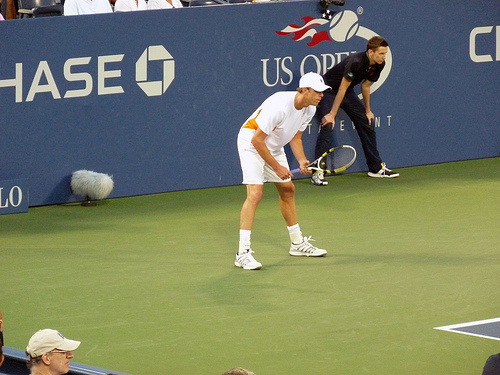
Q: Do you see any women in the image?
A: No, there are no women.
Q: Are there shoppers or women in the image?
A: No, there are no women or shoppers.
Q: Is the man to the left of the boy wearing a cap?
A: Yes, the man is wearing a cap.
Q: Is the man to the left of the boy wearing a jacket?
A: No, the man is wearing a cap.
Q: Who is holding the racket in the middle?
A: The man is holding the tennis racket.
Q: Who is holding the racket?
A: The man is holding the tennis racket.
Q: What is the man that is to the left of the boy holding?
A: The man is holding the racket.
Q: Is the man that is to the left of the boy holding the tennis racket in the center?
A: Yes, the man is holding the tennis racket.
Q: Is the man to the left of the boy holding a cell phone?
A: No, the man is holding the tennis racket.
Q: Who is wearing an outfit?
A: The man is wearing an outfit.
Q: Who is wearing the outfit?
A: The man is wearing an outfit.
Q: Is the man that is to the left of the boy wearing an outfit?
A: Yes, the man is wearing an outfit.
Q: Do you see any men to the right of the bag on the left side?
A: Yes, there is a man to the right of the bag.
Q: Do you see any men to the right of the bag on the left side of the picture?
A: Yes, there is a man to the right of the bag.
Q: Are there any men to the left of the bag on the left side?
A: No, the man is to the right of the bag.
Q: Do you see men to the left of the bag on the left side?
A: No, the man is to the right of the bag.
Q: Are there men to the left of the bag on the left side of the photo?
A: No, the man is to the right of the bag.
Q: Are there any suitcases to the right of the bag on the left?
A: No, there is a man to the right of the bag.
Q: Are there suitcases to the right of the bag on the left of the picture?
A: No, there is a man to the right of the bag.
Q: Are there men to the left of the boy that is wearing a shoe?
A: Yes, there is a man to the left of the boy.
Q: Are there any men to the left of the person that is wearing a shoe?
A: Yes, there is a man to the left of the boy.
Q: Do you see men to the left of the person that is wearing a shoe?
A: Yes, there is a man to the left of the boy.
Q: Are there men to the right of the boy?
A: No, the man is to the left of the boy.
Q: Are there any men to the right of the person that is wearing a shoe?
A: No, the man is to the left of the boy.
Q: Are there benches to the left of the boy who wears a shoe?
A: No, there is a man to the left of the boy.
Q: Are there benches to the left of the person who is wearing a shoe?
A: No, there is a man to the left of the boy.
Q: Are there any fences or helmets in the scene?
A: No, there are no fences or helmets.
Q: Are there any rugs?
A: No, there are no rugs.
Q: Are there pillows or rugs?
A: No, there are no rugs or pillows.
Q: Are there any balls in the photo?
A: Yes, there is a ball.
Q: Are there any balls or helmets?
A: Yes, there is a ball.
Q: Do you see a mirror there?
A: No, there are no mirrors.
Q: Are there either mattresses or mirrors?
A: No, there are no mirrors or mattresses.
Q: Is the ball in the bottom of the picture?
A: No, the ball is in the top of the image.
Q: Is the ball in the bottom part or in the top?
A: The ball is in the top of the image.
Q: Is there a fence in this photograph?
A: No, there are no fences.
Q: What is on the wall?
A: The logo is on the wall.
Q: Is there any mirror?
A: No, there are no mirrors.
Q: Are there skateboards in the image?
A: No, there are no skateboards.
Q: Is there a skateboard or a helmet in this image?
A: No, there are no skateboards or helmets.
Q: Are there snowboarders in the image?
A: No, there are no snowboarders.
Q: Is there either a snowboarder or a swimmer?
A: No, there are no snowboarders or swimmers.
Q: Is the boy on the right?
A: Yes, the boy is on the right of the image.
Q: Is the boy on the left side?
A: No, the boy is on the right of the image.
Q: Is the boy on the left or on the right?
A: The boy is on the right of the image.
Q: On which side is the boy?
A: The boy is on the right of the image.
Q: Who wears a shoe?
A: The boy wears a shoe.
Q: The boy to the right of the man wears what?
A: The boy wears a shoe.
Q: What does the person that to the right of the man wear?
A: The boy wears a shoe.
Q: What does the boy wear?
A: The boy wears a shoe.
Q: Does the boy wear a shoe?
A: Yes, the boy wears a shoe.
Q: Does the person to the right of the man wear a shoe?
A: Yes, the boy wears a shoe.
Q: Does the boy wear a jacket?
A: No, the boy wears a shoe.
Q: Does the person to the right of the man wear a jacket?
A: No, the boy wears a shoe.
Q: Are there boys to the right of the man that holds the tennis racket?
A: Yes, there is a boy to the right of the man.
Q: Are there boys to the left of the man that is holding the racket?
A: No, the boy is to the right of the man.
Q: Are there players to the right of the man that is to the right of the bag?
A: No, there is a boy to the right of the man.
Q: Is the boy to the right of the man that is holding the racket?
A: Yes, the boy is to the right of the man.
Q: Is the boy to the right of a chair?
A: No, the boy is to the right of the man.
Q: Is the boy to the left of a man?
A: No, the boy is to the right of a man.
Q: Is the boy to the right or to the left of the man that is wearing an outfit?
A: The boy is to the right of the man.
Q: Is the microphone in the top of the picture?
A: Yes, the microphone is in the top of the image.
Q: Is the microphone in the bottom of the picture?
A: No, the microphone is in the top of the image.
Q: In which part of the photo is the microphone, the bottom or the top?
A: The microphone is in the top of the image.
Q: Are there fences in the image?
A: No, there are no fences.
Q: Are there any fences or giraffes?
A: No, there are no fences or giraffes.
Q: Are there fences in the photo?
A: No, there are no fences.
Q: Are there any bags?
A: Yes, there is a bag.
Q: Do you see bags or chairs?
A: Yes, there is a bag.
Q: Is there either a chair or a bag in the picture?
A: Yes, there is a bag.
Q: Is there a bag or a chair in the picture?
A: Yes, there is a bag.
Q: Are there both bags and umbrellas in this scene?
A: No, there is a bag but no umbrellas.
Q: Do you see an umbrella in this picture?
A: No, there are no umbrellas.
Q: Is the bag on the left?
A: Yes, the bag is on the left of the image.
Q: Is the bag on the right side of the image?
A: No, the bag is on the left of the image.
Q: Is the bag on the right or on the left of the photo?
A: The bag is on the left of the image.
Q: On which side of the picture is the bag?
A: The bag is on the left of the image.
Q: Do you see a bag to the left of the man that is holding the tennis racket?
A: Yes, there is a bag to the left of the man.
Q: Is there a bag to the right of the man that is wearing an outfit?
A: No, the bag is to the left of the man.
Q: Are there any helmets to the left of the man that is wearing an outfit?
A: No, there is a bag to the left of the man.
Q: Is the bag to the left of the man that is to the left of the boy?
A: Yes, the bag is to the left of the man.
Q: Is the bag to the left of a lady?
A: No, the bag is to the left of the man.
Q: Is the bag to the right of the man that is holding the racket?
A: No, the bag is to the left of the man.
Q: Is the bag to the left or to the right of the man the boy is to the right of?
A: The bag is to the left of the man.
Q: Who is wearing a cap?
A: The man is wearing a cap.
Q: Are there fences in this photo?
A: No, there are no fences.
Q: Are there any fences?
A: No, there are no fences.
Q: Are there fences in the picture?
A: No, there are no fences.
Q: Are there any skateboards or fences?
A: No, there are no fences or skateboards.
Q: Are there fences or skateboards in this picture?
A: No, there are no fences or skateboards.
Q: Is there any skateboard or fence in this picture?
A: No, there are no fences or skateboards.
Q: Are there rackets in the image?
A: Yes, there is a racket.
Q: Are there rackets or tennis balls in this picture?
A: Yes, there is a racket.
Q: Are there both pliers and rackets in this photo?
A: No, there is a racket but no pliers.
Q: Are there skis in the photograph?
A: No, there are no skis.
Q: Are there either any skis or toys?
A: No, there are no skis or toys.